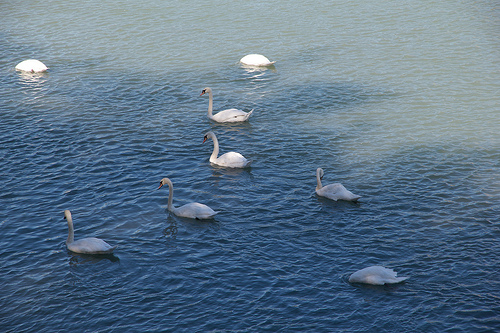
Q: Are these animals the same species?
A: Yes, all the animals are birds.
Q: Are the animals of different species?
A: No, all the animals are birds.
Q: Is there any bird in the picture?
A: Yes, there is a bird.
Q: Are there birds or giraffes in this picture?
A: Yes, there is a bird.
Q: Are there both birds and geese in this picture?
A: No, there is a bird but no geese.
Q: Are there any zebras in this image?
A: No, there are no zebras.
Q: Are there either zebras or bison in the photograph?
A: No, there are no zebras or bison.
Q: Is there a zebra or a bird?
A: Yes, there is a bird.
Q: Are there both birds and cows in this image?
A: No, there is a bird but no cows.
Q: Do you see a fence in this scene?
A: No, there are no fences.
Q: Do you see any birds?
A: Yes, there is a bird.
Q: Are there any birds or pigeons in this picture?
A: Yes, there is a bird.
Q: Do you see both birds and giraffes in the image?
A: No, there is a bird but no giraffes.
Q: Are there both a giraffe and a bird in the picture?
A: No, there is a bird but no giraffes.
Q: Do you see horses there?
A: No, there are no horses.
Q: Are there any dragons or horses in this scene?
A: No, there are no horses or dragons.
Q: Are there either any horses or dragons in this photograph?
A: No, there are no horses or dragons.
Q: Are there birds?
A: Yes, there is a bird.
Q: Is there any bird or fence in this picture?
A: Yes, there is a bird.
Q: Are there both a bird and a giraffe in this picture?
A: No, there is a bird but no giraffes.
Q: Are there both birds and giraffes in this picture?
A: No, there is a bird but no giraffes.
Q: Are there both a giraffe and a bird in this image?
A: No, there is a bird but no giraffes.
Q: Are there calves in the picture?
A: No, there are no calves.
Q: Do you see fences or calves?
A: No, there are no calves or fences.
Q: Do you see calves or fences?
A: No, there are no calves or fences.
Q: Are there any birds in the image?
A: Yes, there is a bird.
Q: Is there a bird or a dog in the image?
A: Yes, there is a bird.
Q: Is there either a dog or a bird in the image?
A: Yes, there is a bird.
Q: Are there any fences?
A: No, there are no fences.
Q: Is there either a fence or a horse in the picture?
A: No, there are no fences or horses.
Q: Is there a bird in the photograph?
A: Yes, there is a bird.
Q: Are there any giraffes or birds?
A: Yes, there is a bird.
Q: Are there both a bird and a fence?
A: No, there is a bird but no fences.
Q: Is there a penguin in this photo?
A: No, there are no penguins.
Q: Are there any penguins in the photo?
A: No, there are no penguins.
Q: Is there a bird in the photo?
A: Yes, there are birds.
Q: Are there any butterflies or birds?
A: Yes, there are birds.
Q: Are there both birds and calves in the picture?
A: No, there are birds but no calves.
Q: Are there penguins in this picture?
A: No, there are no penguins.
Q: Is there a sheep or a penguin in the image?
A: No, there are no penguins or sheep.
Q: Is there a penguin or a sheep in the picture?
A: No, there are no penguins or sheep.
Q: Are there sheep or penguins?
A: No, there are no penguins or sheep.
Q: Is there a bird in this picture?
A: Yes, there is a bird.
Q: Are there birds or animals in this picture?
A: Yes, there is a bird.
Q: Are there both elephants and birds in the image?
A: No, there is a bird but no elephants.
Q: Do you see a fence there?
A: No, there are no fences.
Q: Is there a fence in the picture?
A: No, there are no fences.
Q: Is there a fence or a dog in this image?
A: No, there are no fences or dogs.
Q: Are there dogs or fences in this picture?
A: No, there are no fences or dogs.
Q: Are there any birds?
A: Yes, there is a bird.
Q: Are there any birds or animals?
A: Yes, there is a bird.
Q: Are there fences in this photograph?
A: No, there are no fences.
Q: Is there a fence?
A: No, there are no fences.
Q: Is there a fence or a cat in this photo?
A: No, there are no fences or cats.